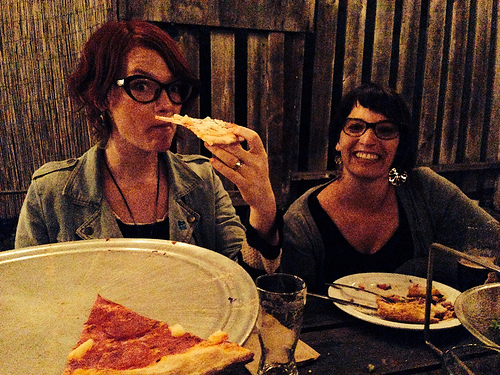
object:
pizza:
[68, 293, 255, 375]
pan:
[2, 238, 260, 374]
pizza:
[156, 115, 252, 148]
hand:
[202, 125, 273, 204]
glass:
[252, 273, 308, 374]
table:
[301, 304, 500, 375]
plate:
[329, 271, 465, 330]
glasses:
[111, 74, 196, 105]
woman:
[14, 19, 282, 278]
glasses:
[341, 117, 404, 140]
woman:
[280, 84, 499, 294]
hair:
[69, 18, 201, 147]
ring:
[231, 159, 243, 171]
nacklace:
[99, 153, 165, 239]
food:
[377, 282, 454, 323]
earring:
[388, 167, 410, 187]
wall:
[1, 2, 497, 249]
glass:
[456, 218, 500, 279]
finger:
[206, 156, 246, 186]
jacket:
[13, 141, 281, 286]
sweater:
[279, 167, 500, 305]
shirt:
[310, 179, 414, 295]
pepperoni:
[105, 311, 155, 340]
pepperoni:
[105, 341, 150, 371]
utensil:
[309, 292, 378, 309]